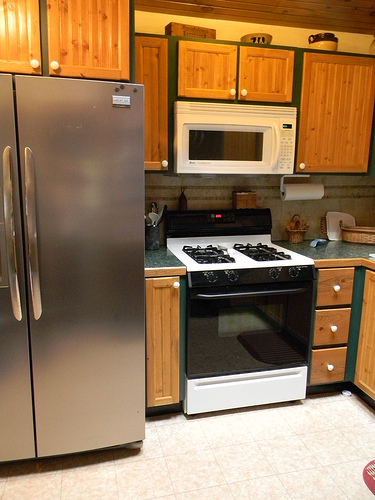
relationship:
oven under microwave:
[161, 207, 316, 415] [173, 100, 299, 175]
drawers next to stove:
[310, 247, 355, 401] [148, 194, 323, 413]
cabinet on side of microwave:
[133, 35, 167, 172] [173, 100, 299, 175]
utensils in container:
[145, 200, 166, 226] [145, 224, 161, 250]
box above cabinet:
[164, 20, 215, 39] [298, 48, 371, 171]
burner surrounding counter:
[195, 257, 232, 266] [271, 238, 373, 264]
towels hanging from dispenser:
[286, 184, 324, 202] [280, 175, 311, 195]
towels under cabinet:
[286, 184, 324, 202] [296, 44, 373, 176]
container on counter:
[145, 224, 161, 250] [142, 242, 187, 279]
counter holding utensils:
[142, 242, 187, 279] [142, 198, 169, 230]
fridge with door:
[0, 71, 146, 462] [16, 70, 150, 456]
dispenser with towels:
[278, 172, 311, 194] [281, 183, 326, 200]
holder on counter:
[308, 237, 326, 247] [271, 238, 373, 264]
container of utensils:
[143, 226, 165, 252] [285, 215, 310, 236]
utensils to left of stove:
[285, 215, 310, 236] [179, 207, 320, 413]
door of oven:
[182, 278, 310, 377] [160, 198, 321, 424]